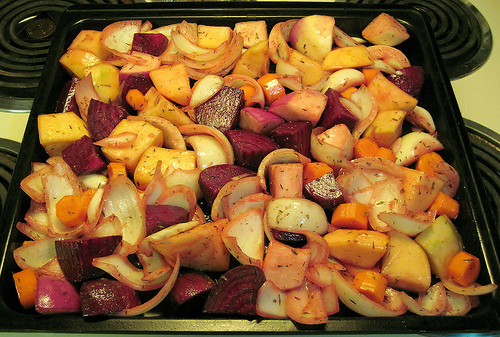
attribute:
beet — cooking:
[128, 27, 171, 60]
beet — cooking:
[83, 92, 133, 146]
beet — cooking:
[192, 81, 249, 141]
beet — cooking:
[195, 162, 264, 209]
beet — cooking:
[197, 260, 270, 322]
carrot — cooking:
[124, 87, 151, 115]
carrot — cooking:
[51, 192, 93, 231]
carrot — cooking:
[9, 265, 46, 312]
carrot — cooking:
[327, 200, 377, 235]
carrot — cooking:
[442, 247, 485, 290]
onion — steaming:
[260, 241, 313, 293]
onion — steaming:
[96, 17, 144, 64]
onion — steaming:
[88, 247, 181, 295]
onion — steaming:
[183, 70, 227, 118]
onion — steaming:
[167, 23, 234, 66]